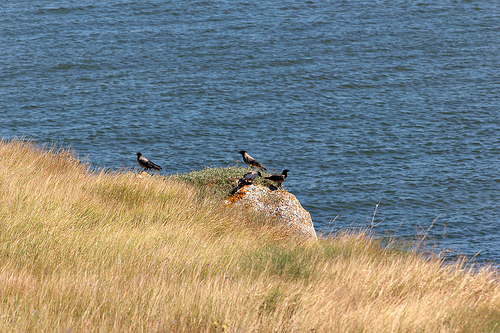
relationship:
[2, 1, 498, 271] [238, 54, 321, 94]
water has ripples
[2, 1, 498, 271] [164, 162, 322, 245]
water has a rock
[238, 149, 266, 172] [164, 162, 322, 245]
bird on a rock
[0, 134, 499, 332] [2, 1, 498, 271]
grass near water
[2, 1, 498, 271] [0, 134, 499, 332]
water near grass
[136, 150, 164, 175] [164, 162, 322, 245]
lichen on a rock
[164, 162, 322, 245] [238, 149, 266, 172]
rock has a bird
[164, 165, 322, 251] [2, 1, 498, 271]
cliff near water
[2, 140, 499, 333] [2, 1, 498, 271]
meadow near water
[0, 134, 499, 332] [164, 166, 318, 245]
grass near rock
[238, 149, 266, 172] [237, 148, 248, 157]
bird has a head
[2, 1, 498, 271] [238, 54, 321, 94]
water has a ripples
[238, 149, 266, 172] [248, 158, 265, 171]
bird has a wing